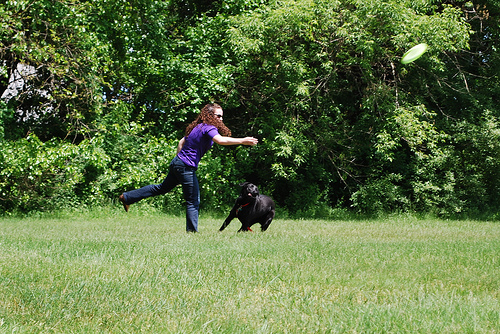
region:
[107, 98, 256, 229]
lady in a purple shirt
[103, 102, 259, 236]
lady with brown hair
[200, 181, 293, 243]
black dog in field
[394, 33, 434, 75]
green frisbee in the air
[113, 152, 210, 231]
pair of blue jeans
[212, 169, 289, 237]
black dog running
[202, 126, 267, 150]
arm of the lady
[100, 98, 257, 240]
lady throwing a frisbee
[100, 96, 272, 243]
lady with brown shoes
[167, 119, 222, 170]
a purple shirt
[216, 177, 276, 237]
black dog playing frisbee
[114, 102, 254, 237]
woman playing frisbee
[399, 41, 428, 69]
frisbee flying in the air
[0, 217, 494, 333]
grassy field area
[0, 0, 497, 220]
background full of green trees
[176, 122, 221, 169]
purple shirt on woman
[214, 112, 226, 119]
black sunglasses on woman's face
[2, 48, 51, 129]
area of blue sky through the trees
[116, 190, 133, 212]
left foot of woman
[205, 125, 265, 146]
right arm of woman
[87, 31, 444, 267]
the girl is throwing the frisbee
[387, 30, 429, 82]
the frisbee is green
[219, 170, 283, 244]
the dog is black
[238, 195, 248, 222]
the dog is wearing a leash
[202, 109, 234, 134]
her hair is long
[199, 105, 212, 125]
her hair is red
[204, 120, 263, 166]
her arm is extended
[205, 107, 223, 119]
the girl is wearing sunglasses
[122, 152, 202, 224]
the girl is wearing jeans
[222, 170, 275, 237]
the dog is playing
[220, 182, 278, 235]
a black dog in a field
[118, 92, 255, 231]
a woman throwing a frisbee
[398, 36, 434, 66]
a green frisbee in the air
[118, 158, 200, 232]
a pair of blue jeans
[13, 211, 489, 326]
a grassy field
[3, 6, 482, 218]
a row of trees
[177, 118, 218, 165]
a purple tee shirt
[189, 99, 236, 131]
a womans curly red hair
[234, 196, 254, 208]
a red dog collar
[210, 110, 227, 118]
a pair of sunglasses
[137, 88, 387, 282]
the dog is black and visible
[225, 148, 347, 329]
the dog is black and visible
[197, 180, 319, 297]
the dog is black and visible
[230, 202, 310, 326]
the dog is black and visible